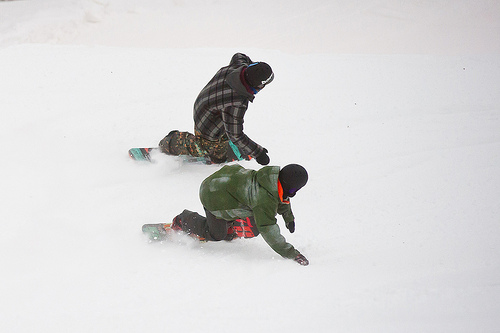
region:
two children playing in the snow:
[128, 45, 323, 270]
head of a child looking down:
[238, 56, 273, 93]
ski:
[123, 143, 188, 164]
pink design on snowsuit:
[227, 212, 252, 234]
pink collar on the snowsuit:
[270, 178, 291, 203]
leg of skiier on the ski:
[167, 205, 228, 245]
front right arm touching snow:
[245, 190, 311, 266]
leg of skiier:
[153, 126, 218, 162]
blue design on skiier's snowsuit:
[228, 140, 244, 160]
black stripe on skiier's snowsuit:
[191, 85, 246, 114]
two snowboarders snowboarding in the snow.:
[120, 42, 315, 282]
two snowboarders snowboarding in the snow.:
[125, 45, 315, 280]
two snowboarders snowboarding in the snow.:
[115, 35, 315, 280]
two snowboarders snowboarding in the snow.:
[111, 41, 312, 282]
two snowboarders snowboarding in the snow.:
[120, 40, 315, 275]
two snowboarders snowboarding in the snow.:
[120, 40, 320, 280]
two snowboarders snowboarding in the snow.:
[120, 35, 315, 285]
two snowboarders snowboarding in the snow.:
[115, 45, 321, 285]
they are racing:
[112, 34, 402, 301]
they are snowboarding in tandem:
[103, 27, 426, 330]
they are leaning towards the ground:
[100, 28, 456, 329]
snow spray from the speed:
[132, 133, 241, 272]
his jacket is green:
[176, 163, 358, 253]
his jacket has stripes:
[174, 35, 298, 186]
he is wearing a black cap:
[262, 141, 348, 230]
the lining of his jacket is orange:
[274, 165, 294, 213]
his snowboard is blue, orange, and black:
[124, 125, 301, 177]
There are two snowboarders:
[117, 46, 342, 287]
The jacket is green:
[202, 163, 331, 273]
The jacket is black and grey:
[179, 50, 287, 168]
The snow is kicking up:
[154, 211, 223, 268]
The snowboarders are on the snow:
[120, 25, 355, 280]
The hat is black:
[276, 162, 314, 199]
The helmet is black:
[239, 50, 278, 94]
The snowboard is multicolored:
[114, 135, 276, 165]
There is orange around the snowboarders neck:
[264, 163, 299, 226]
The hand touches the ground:
[263, 226, 328, 294]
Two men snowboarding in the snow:
[125, 49, 310, 270]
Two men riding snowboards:
[124, 51, 310, 271]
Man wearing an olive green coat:
[170, 162, 309, 267]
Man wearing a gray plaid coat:
[157, 50, 275, 165]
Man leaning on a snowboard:
[138, 162, 310, 267]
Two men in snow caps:
[159, 52, 311, 269]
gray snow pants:
[174, 203, 226, 244]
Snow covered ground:
[2, 0, 499, 331]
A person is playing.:
[166, 164, 333, 256]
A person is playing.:
[163, 42, 295, 177]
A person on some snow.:
[140, 53, 277, 163]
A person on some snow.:
[178, 162, 319, 262]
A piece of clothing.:
[198, 157, 296, 264]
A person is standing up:
[156, 39, 288, 168]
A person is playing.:
[158, 57, 268, 167]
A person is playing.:
[176, 159, 329, 271]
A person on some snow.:
[167, 47, 279, 176]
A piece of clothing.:
[201, 152, 297, 274]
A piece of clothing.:
[277, 162, 298, 199]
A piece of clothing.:
[246, 66, 276, 92]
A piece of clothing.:
[187, 52, 268, 157]